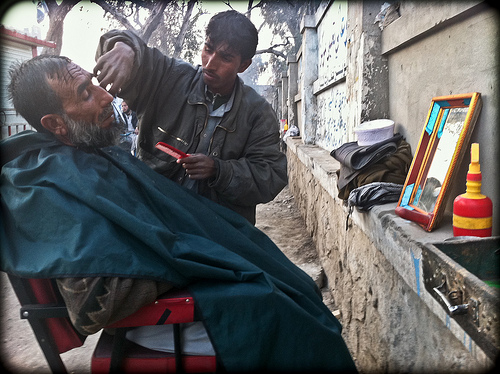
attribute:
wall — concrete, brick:
[277, 37, 499, 370]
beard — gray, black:
[56, 115, 129, 148]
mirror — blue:
[383, 93, 498, 223]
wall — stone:
[272, 125, 498, 371]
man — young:
[94, 16, 293, 209]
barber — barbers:
[93, 6, 288, 228]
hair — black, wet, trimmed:
[9, 52, 74, 128]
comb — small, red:
[151, 139, 211, 169]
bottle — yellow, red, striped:
[450, 135, 492, 233]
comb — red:
[150, 132, 198, 164]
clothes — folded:
[346, 120, 416, 214]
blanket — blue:
[5, 132, 313, 334]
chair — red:
[12, 264, 214, 372]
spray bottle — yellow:
[452, 132, 493, 240]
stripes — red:
[446, 185, 498, 235]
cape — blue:
[7, 132, 363, 372]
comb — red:
[155, 140, 186, 159]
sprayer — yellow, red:
[453, 140, 494, 238]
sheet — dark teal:
[1, 124, 363, 372]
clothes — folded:
[332, 112, 405, 210]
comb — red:
[116, 127, 203, 172]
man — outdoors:
[98, 8, 264, 168]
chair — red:
[4, 180, 242, 369]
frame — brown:
[389, 88, 483, 231]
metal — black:
[32, 327, 57, 368]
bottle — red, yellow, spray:
[452, 146, 484, 231]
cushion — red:
[32, 277, 72, 347]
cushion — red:
[88, 330, 208, 367]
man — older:
[14, 58, 173, 368]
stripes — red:
[454, 201, 477, 211]